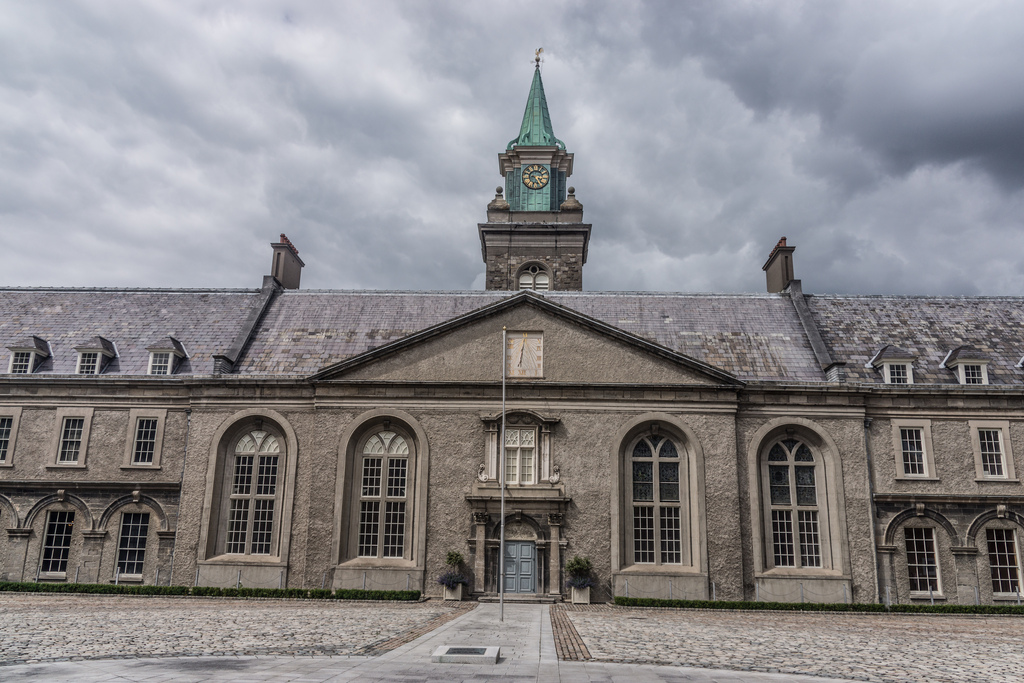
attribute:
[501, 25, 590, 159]
top — green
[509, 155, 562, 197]
clock — round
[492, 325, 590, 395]
clock — square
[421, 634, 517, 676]
drain — concrete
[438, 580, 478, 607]
pot — concrete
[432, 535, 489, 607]
plant — green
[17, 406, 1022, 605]
windows — many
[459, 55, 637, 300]
tower — green, colored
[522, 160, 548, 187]
face — clock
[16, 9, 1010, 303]
clouds — grey, colored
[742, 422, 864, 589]
window — old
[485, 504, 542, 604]
door — grey, colored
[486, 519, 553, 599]
door — gray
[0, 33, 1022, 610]
building — old, large, tan, stone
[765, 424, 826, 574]
window — large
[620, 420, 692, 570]
window — large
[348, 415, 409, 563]
window — large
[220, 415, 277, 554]
window — large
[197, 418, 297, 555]
window — large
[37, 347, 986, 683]
building — stone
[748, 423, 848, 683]
window — large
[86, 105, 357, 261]
clouds — gray and white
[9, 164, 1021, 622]
building — large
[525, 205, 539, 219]
tower — green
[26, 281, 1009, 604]
building — large, long, stone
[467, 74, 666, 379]
steeple — green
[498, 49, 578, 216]
steeple — green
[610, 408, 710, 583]
window — large